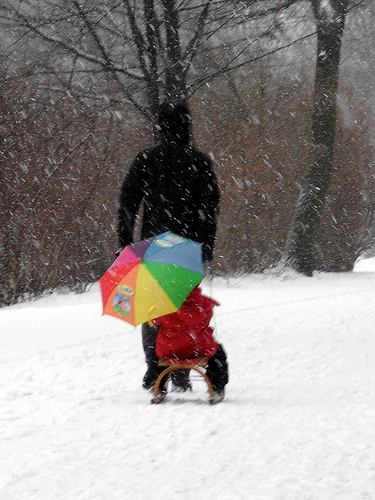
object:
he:
[115, 91, 231, 398]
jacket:
[112, 96, 222, 263]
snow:
[0, 254, 375, 500]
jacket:
[151, 282, 220, 371]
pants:
[143, 348, 230, 385]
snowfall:
[32, 90, 360, 242]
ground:
[0, 256, 375, 499]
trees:
[5, 0, 243, 102]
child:
[142, 283, 229, 399]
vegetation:
[192, 73, 374, 277]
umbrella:
[98, 228, 206, 329]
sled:
[148, 359, 225, 403]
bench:
[151, 358, 225, 406]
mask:
[158, 102, 190, 152]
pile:
[259, 260, 311, 283]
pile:
[309, 267, 337, 278]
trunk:
[273, 1, 350, 277]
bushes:
[2, 0, 375, 309]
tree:
[260, 0, 373, 278]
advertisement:
[111, 283, 135, 318]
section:
[104, 261, 141, 325]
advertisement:
[155, 233, 188, 249]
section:
[142, 227, 203, 258]